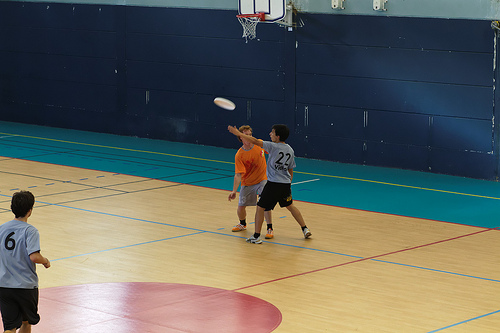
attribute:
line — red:
[315, 233, 403, 287]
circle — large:
[1, 273, 284, 332]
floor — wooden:
[4, 144, 487, 331]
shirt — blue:
[256, 137, 304, 190]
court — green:
[1, 114, 497, 331]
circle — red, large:
[1, 282, 281, 331]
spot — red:
[38, 272, 288, 331]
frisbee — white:
[210, 93, 237, 111]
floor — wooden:
[2, 113, 498, 328]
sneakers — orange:
[230, 219, 277, 239]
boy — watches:
[9, 179, 70, 321]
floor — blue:
[9, 116, 486, 258]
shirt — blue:
[1, 217, 38, 292]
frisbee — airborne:
[210, 94, 236, 114]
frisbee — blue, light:
[214, 97, 236, 111]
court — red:
[36, 69, 498, 329]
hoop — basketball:
[228, 7, 293, 38]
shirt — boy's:
[258, 138, 294, 183]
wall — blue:
[372, 27, 497, 174]